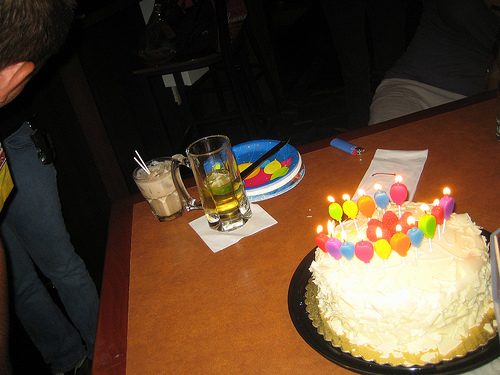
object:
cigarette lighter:
[330, 137, 365, 156]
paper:
[351, 148, 428, 203]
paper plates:
[203, 139, 306, 203]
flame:
[316, 224, 322, 233]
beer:
[199, 169, 248, 233]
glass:
[170, 135, 251, 233]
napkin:
[187, 204, 278, 253]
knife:
[234, 136, 291, 182]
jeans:
[0, 121, 100, 372]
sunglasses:
[25, 116, 54, 164]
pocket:
[4, 139, 35, 162]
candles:
[315, 181, 455, 264]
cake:
[307, 201, 498, 367]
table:
[95, 84, 499, 374]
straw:
[133, 156, 151, 174]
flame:
[373, 183, 383, 191]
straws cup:
[135, 150, 150, 173]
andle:
[342, 214, 476, 278]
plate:
[287, 228, 499, 374]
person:
[0, 1, 99, 374]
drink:
[135, 161, 183, 217]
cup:
[133, 156, 183, 222]